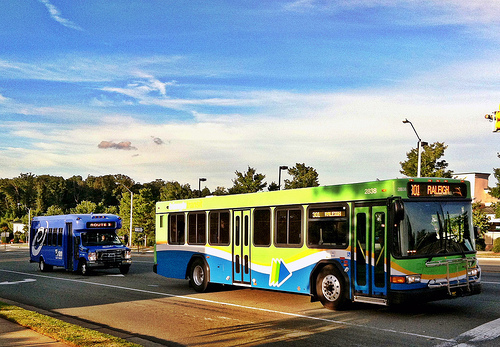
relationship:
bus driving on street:
[10, 173, 498, 318] [0, 245, 497, 345]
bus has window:
[151, 180, 479, 304] [187, 212, 207, 243]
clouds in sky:
[94, 132, 173, 158] [1, 0, 499, 191]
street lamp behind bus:
[400, 116, 422, 177] [150, 175, 481, 312]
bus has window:
[151, 180, 479, 304] [167, 213, 177, 240]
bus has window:
[151, 180, 479, 304] [388, 195, 473, 255]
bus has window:
[151, 180, 479, 304] [168, 210, 353, 250]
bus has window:
[151, 180, 479, 304] [36, 227, 63, 244]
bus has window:
[151, 180, 479, 304] [82, 227, 118, 244]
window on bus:
[275, 206, 287, 246] [150, 175, 481, 312]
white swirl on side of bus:
[155, 241, 351, 279] [140, 0, 482, 132]